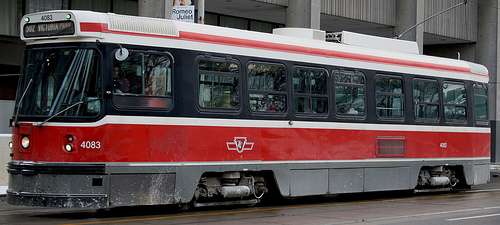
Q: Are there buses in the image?
A: Yes, there is a bus.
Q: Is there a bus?
A: Yes, there is a bus.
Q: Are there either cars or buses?
A: Yes, there is a bus.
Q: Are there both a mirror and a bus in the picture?
A: Yes, there are both a bus and a mirror.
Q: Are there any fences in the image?
A: No, there are no fences.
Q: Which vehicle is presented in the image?
A: The vehicle is a bus.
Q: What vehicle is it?
A: The vehicle is a bus.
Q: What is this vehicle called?
A: This is a bus.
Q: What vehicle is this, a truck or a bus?
A: This is a bus.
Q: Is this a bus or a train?
A: This is a bus.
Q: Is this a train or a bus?
A: This is a bus.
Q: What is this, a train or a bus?
A: This is a bus.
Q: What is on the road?
A: The bus is on the road.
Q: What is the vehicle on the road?
A: The vehicle is a bus.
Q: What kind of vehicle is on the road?
A: The vehicle is a bus.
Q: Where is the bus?
A: The bus is on the road.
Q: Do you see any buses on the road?
A: Yes, there is a bus on the road.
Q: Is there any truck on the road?
A: No, there is a bus on the road.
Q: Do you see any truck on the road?
A: No, there is a bus on the road.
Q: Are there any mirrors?
A: Yes, there is a mirror.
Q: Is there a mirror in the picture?
A: Yes, there is a mirror.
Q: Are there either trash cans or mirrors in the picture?
A: Yes, there is a mirror.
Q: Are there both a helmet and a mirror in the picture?
A: No, there is a mirror but no helmets.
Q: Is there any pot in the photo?
A: No, there are no pots.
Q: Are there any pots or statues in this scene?
A: No, there are no pots or statues.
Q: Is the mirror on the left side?
A: Yes, the mirror is on the left of the image.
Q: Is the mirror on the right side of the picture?
A: No, the mirror is on the left of the image.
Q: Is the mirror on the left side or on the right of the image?
A: The mirror is on the left of the image.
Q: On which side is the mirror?
A: The mirror is on the left of the image.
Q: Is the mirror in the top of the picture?
A: Yes, the mirror is in the top of the image.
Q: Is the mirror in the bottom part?
A: No, the mirror is in the top of the image.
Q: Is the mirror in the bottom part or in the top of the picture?
A: The mirror is in the top of the image.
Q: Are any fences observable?
A: No, there are no fences.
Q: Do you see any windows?
A: Yes, there is a window.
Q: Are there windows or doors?
A: Yes, there is a window.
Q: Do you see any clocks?
A: No, there are no clocks.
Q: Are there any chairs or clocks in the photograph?
A: No, there are no clocks or chairs.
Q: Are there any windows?
A: Yes, there is a window.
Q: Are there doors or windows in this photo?
A: Yes, there is a window.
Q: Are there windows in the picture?
A: Yes, there is a window.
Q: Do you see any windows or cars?
A: Yes, there is a window.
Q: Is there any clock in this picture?
A: No, there are no clocks.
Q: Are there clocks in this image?
A: No, there are no clocks.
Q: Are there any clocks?
A: No, there are no clocks.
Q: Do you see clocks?
A: No, there are no clocks.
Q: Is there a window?
A: Yes, there is a window.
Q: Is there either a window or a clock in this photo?
A: Yes, there is a window.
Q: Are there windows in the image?
A: Yes, there is a window.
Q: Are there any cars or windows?
A: Yes, there is a window.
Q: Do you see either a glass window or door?
A: Yes, there is a glass window.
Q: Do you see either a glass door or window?
A: Yes, there is a glass window.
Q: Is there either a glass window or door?
A: Yes, there is a glass window.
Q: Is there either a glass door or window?
A: Yes, there is a glass window.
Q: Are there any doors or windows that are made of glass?
A: Yes, the window is made of glass.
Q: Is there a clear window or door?
A: Yes, there is a clear window.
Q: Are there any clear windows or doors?
A: Yes, there is a clear window.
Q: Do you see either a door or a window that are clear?
A: Yes, the window is clear.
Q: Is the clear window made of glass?
A: Yes, the window is made of glass.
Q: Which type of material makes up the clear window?
A: The window is made of glass.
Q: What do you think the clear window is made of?
A: The window is made of glass.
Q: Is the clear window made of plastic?
A: No, the window is made of glass.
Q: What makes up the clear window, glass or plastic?
A: The window is made of glass.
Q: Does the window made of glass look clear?
A: Yes, the window is clear.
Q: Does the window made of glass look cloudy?
A: No, the window is clear.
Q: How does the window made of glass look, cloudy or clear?
A: The window is clear.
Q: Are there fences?
A: No, there are no fences.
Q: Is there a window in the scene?
A: Yes, there is a window.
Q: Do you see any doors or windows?
A: Yes, there is a window.